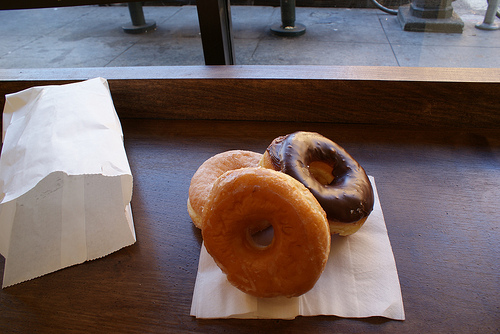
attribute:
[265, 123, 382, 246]
donut — chocolate, frosted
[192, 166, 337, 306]
donut — glazed, standing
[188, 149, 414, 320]
napkin — white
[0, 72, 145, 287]
bag — white, empty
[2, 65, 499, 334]
counter — brown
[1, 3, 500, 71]
sidewalk — concrete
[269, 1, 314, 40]
post — metal